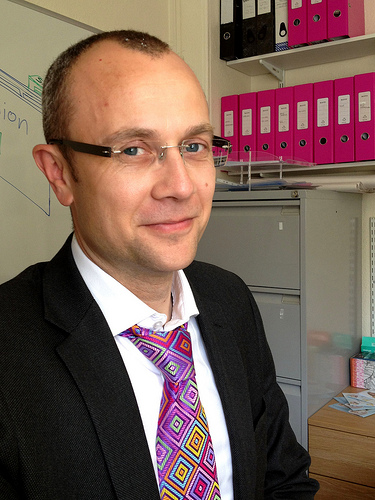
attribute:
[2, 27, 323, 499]
man — posing, smiling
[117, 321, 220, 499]
tie — multicolored, colorful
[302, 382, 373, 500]
table — wooden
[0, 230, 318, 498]
coat — black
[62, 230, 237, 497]
shirt — white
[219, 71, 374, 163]
color — oink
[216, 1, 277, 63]
color — black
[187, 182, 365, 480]
cupboard — metallic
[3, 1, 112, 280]
board — white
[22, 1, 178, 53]
color — cream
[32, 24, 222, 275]
head — bald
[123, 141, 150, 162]
eye — green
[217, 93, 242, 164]
binder — pink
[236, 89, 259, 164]
binder — pink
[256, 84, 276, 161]
binder — pink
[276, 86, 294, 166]
binder — pink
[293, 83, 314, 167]
binder — pink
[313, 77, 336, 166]
binder — pink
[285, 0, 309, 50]
binder — red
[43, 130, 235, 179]
frame — black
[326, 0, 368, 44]
file — red